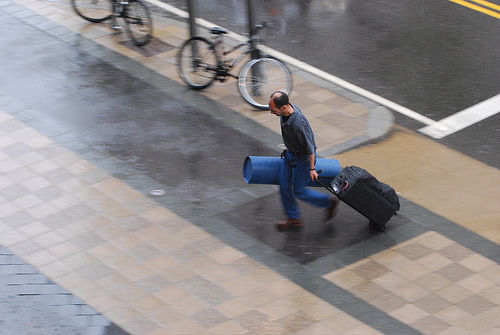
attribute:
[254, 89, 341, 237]
man — partially-bald , walking, close, white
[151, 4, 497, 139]
road — grey, flat, yellow, black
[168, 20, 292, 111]
bike — leaning , black, parked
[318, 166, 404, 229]
suitcase — black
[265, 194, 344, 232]
shoes — brown, blurry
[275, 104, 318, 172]
shirt — blue, short-sleeved 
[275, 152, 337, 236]
jeans — blue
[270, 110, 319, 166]
shirt — grey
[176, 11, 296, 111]
bike — leaned 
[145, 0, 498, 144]
lines painted — white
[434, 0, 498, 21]
lines painted — yellow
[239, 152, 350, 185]
container — blue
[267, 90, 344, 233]
man — balding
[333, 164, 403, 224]
suitcase — black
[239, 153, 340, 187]
tube — blue, large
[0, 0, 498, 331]
sidewalk — wet